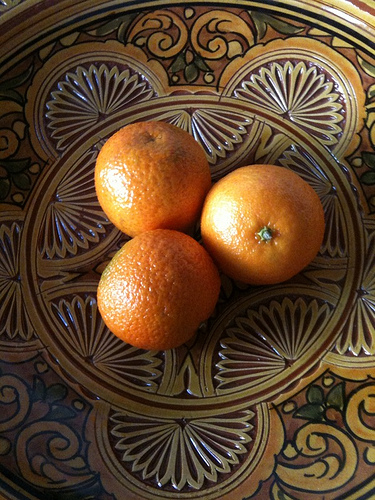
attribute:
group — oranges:
[84, 122, 331, 356]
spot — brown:
[130, 118, 187, 165]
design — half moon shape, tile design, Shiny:
[96, 404, 272, 498]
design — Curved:
[190, 7, 256, 59]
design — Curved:
[125, 7, 190, 59]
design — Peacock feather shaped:
[107, 409, 258, 488]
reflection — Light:
[209, 194, 238, 238]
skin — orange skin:
[200, 163, 327, 283]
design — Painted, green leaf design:
[288, 380, 345, 418]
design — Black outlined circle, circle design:
[278, 398, 297, 415]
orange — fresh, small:
[201, 164, 327, 281]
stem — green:
[256, 223, 275, 242]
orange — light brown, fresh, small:
[94, 119, 209, 236]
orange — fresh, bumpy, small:
[97, 228, 223, 354]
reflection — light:
[100, 160, 138, 207]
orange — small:
[87, 227, 224, 351]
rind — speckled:
[97, 228, 215, 345]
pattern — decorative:
[17, 418, 97, 490]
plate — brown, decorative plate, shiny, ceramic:
[0, 2, 372, 499]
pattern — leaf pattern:
[293, 383, 346, 422]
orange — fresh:
[96, 235, 220, 350]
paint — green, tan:
[106, 0, 258, 96]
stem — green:
[251, 221, 280, 247]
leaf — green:
[289, 373, 348, 420]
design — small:
[282, 396, 301, 413]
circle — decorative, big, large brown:
[24, 96, 364, 414]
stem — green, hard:
[255, 223, 279, 242]